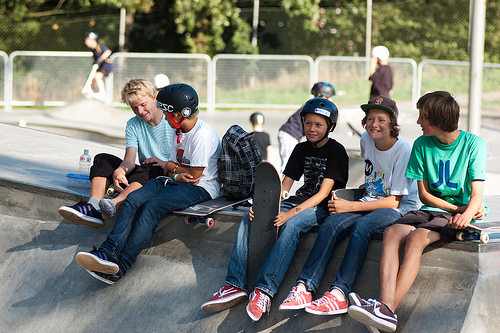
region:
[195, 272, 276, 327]
RED AND WHITE SNEAKERS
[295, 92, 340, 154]
BLACK SAFETY HELMET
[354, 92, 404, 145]
BROWN CAP ON BOYS HEAD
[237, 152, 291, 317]
BLACK SKATE BOARD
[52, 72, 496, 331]
FIVE BOYS SITTING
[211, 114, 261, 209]
CHECKED BACK PACK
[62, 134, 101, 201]
WATER BOTTLE NEXT TO LUNCHBOX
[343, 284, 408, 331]
BROWN AND WHITE SNEAKERS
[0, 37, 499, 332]
BOYS HANGING OUT AT SKATEBOARD RING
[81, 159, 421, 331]
THREE BOYS WEARING PANTS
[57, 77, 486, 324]
Several children sitting outdoors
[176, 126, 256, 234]
A skateboard and a backpack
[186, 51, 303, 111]
A piece of grey fence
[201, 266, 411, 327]
Three people wearing sneakers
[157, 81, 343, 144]
Four people with black helmets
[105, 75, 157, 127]
A boy with blonde hair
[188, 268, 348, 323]
Two people with red shoes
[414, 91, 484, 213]
A boy in a green shirt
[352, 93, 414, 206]
A boy in a brown cap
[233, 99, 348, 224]
A boy holding a skateboard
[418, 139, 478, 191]
Teal shirt with blue design on front of it.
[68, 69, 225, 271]
Boys with matching black and blue striped sneakers.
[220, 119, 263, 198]
Plaid back pack positioned on top of skateboard.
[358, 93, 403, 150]
Head of boy wearing a brown baseball cap.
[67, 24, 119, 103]
Kid on scooter in background.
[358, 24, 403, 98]
Kid in background wearing a brown t-shirt.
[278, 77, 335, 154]
Kid in background wearing a black helmet with the color light blue on top.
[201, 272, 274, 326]
Red sneakers on boy with black helmet.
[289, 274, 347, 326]
Red sneakers with three stripes on them.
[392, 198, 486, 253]
Brown shorts worn by boy with brown hair at the end of the ramp.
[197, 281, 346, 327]
RED AND WHITE SNEAKERS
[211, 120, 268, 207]
CHECKERED BACK PACK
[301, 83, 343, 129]
BLACK HARD HELMET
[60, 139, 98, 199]
WATER BOTTLE AND LUNCH BOX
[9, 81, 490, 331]
FIVE BOYS SITTING ON SKATING RING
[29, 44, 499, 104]
FENCE AROUND SKATING RING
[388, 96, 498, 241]
BOY WEARING GREEN T-SHIRT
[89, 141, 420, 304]
THREE BOYS WEARING JEANS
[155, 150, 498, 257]
FOUR SKATE BOARDS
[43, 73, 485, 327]
Boys sitting on side of skateboard rink.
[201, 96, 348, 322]
Boy holding his skateboard.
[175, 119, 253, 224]
Skateboard with book bag on top.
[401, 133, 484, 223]
A boy wearing green shirt.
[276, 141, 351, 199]
A boy wearing black shirt.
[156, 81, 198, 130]
Boy wearing black helmet.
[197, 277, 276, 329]
A pair of red tennis shoes.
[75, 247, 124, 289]
Black tennis shoes with blue stripes.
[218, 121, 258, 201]
A plaid book bag.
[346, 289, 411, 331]
Feet crossed at ankles.